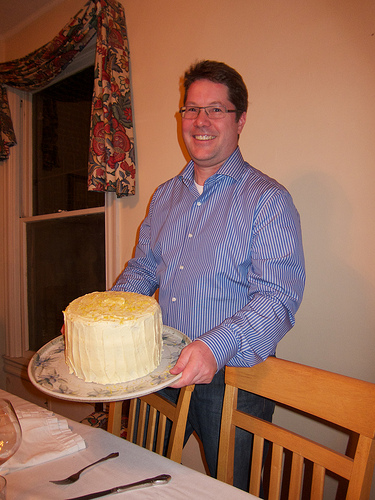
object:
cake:
[63, 290, 163, 385]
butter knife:
[70, 473, 172, 499]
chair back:
[216, 355, 375, 499]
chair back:
[109, 383, 196, 466]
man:
[107, 60, 306, 500]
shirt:
[111, 146, 307, 374]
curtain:
[0, 0, 135, 199]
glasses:
[178, 102, 243, 120]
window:
[21, 42, 106, 362]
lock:
[57, 210, 64, 214]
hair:
[183, 59, 248, 121]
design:
[26, 324, 193, 403]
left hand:
[169, 338, 218, 389]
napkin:
[0, 388, 86, 475]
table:
[0, 389, 262, 500]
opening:
[236, 385, 360, 459]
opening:
[301, 458, 315, 500]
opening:
[322, 467, 348, 500]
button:
[197, 202, 201, 207]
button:
[188, 233, 192, 237]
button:
[180, 265, 184, 270]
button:
[171, 297, 176, 302]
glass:
[0, 400, 22, 467]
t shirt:
[193, 180, 203, 196]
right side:
[87, 2, 137, 199]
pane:
[31, 66, 106, 214]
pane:
[25, 210, 107, 354]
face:
[181, 80, 236, 160]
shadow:
[122, 44, 375, 500]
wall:
[0, 0, 375, 500]